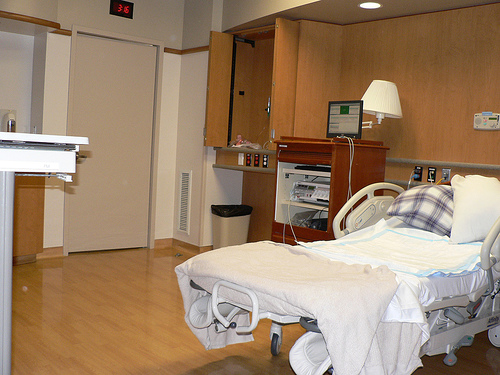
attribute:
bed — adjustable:
[168, 179, 499, 372]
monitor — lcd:
[325, 98, 365, 139]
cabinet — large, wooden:
[269, 131, 391, 244]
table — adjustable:
[0, 129, 90, 374]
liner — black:
[212, 202, 255, 217]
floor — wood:
[13, 247, 500, 373]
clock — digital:
[108, 1, 135, 21]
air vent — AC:
[177, 166, 195, 236]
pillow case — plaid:
[384, 182, 457, 240]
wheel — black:
[267, 322, 284, 360]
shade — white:
[360, 78, 404, 118]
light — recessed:
[357, 0, 384, 14]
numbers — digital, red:
[116, 3, 130, 14]